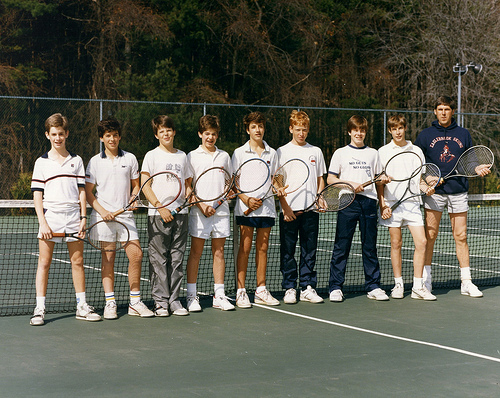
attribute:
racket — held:
[56, 213, 196, 263]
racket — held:
[72, 188, 167, 257]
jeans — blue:
[278, 210, 318, 288]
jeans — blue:
[329, 194, 380, 291]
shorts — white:
[35, 209, 84, 243]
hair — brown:
[433, 94, 453, 112]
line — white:
[30, 249, 499, 362]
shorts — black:
[236, 214, 276, 230]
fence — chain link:
[0, 93, 497, 216]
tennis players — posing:
[28, 97, 499, 324]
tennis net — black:
[0, 191, 499, 315]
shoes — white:
[28, 302, 101, 326]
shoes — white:
[99, 302, 153, 318]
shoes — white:
[152, 301, 187, 316]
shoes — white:
[184, 294, 233, 312]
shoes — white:
[237, 285, 279, 307]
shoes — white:
[283, 285, 323, 303]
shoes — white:
[328, 284, 388, 300]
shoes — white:
[391, 276, 437, 299]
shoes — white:
[423, 279, 483, 297]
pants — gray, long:
[147, 212, 189, 306]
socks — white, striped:
[103, 288, 142, 305]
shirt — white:
[376, 136, 426, 201]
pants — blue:
[325, 193, 385, 292]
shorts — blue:
[240, 212, 276, 231]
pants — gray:
[147, 208, 185, 311]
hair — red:
[288, 107, 310, 127]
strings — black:
[2, 206, 499, 315]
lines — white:
[27, 239, 498, 363]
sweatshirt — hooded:
[414, 120, 482, 195]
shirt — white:
[30, 148, 90, 215]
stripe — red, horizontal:
[30, 171, 84, 185]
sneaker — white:
[30, 303, 48, 328]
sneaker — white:
[75, 306, 99, 322]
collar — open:
[240, 138, 271, 157]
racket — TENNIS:
[212, 153, 270, 214]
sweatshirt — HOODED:
[420, 124, 474, 194]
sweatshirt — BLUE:
[422, 125, 467, 194]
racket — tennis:
[99, 167, 184, 224]